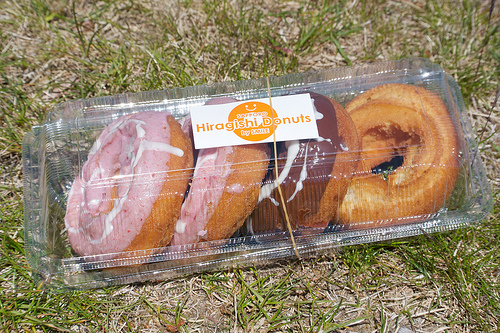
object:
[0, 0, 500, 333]
grass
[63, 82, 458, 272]
donuts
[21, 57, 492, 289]
lid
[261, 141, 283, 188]
band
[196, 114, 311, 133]
letters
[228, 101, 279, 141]
circle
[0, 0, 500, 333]
ground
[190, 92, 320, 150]
label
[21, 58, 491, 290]
case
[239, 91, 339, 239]
frosting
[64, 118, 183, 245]
frosting